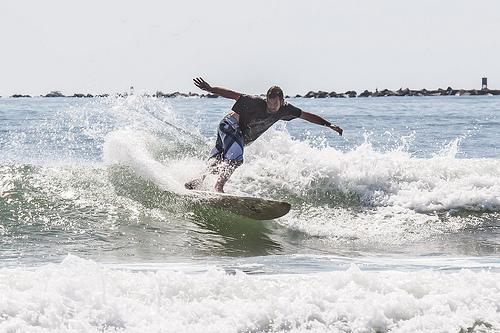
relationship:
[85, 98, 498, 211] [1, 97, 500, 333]
waves in water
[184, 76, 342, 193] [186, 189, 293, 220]
man on surfboard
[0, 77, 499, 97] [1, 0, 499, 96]
shoreline in background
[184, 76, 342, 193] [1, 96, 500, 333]
man at water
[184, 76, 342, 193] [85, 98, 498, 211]
man riding waves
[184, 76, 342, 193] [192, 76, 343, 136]
man has arms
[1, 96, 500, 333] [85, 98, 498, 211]
water has waves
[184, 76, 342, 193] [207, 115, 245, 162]
man wearing shorts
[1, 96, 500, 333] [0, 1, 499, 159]
water in background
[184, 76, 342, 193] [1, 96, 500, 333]
man surfing water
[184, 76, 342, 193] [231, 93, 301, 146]
man wearing shirt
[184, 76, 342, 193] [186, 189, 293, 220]
man riding surfboard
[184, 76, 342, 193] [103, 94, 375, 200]
man riding wave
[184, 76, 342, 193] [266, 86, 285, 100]
man has hair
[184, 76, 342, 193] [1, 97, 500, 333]
man on water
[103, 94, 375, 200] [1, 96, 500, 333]
wave on water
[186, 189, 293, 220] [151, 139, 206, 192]
surfboard has wake